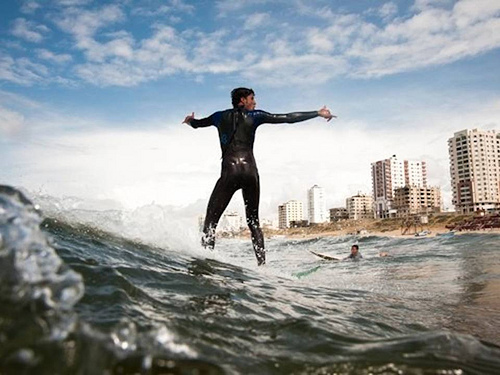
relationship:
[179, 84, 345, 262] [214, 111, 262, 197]
man wearing wet suit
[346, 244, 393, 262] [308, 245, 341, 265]
man on surfboard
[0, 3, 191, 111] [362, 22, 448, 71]
sky has clouds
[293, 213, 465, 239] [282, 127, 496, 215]
beach has hotels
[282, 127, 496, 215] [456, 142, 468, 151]
hotels have windows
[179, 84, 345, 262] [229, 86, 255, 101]
man has hair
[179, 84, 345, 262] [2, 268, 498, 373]
man in ocean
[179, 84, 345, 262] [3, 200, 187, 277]
man catching wave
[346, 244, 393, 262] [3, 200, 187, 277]
man going for wave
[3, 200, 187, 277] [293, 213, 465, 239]
wave hitting beach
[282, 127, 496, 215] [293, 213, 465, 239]
hotels dot beach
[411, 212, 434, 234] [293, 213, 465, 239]
lifeguard stand on beach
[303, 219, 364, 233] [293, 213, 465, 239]
dunes on beach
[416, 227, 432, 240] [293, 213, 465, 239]
boats on beach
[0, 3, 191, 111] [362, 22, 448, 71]
sky with clouds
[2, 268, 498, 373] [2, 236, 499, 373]
ocean in ocean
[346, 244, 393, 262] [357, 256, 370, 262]
man on belly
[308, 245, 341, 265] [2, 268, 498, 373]
surfboard in ocean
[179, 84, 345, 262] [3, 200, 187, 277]
man surfing wave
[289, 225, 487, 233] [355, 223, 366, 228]
shore has soil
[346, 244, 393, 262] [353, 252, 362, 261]
man wearing shirt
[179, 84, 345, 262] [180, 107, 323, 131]
man has arms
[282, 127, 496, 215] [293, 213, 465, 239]
hotels on beach